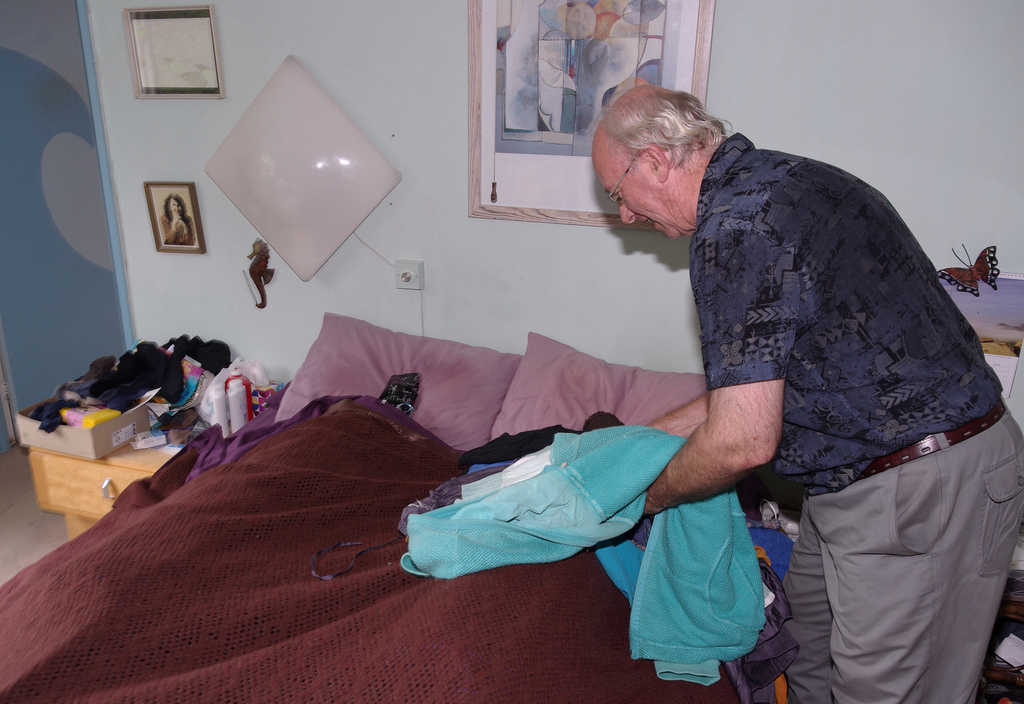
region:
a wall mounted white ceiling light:
[197, 50, 401, 285]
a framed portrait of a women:
[136, 170, 212, 265]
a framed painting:
[466, 0, 719, 229]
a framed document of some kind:
[121, 0, 224, 105]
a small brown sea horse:
[238, 228, 280, 323]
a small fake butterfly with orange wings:
[927, 237, 1007, 310]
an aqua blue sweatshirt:
[396, 421, 771, 690]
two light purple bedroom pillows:
[269, 307, 712, 454]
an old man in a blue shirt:
[583, 73, 1013, 702]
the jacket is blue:
[402, 416, 770, 682]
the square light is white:
[200, 53, 403, 281]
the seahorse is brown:
[242, 239, 278, 310]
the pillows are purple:
[276, 309, 710, 453]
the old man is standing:
[593, 83, 1021, 700]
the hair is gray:
[599, 83, 727, 166]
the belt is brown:
[860, 391, 1010, 478]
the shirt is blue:
[694, 132, 1002, 503]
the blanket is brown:
[1, 410, 739, 701]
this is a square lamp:
[162, 48, 441, 284]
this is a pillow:
[283, 291, 511, 460]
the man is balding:
[476, 47, 783, 288]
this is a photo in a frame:
[133, 133, 222, 266]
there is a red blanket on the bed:
[4, 410, 769, 702]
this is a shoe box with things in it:
[7, 372, 163, 471]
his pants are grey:
[789, 358, 1020, 692]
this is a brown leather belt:
[811, 418, 1017, 501]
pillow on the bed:
[522, 354, 602, 430]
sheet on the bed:
[525, 544, 742, 628]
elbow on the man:
[719, 435, 783, 468]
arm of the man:
[640, 451, 735, 494]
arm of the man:
[631, 411, 696, 441]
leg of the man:
[778, 531, 947, 678]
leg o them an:
[776, 549, 835, 651]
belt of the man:
[924, 436, 951, 455]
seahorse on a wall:
[241, 233, 283, 314]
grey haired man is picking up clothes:
[392, 73, 1022, 702]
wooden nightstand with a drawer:
[20, 405, 217, 555]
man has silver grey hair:
[570, 72, 1022, 702]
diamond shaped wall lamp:
[201, 50, 408, 289]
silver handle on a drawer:
[98, 474, 118, 503]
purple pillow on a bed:
[266, 301, 523, 461]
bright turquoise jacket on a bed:
[397, 416, 771, 693]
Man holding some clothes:
[582, 132, 1012, 684]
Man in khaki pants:
[575, 133, 1010, 690]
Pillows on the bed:
[293, 301, 775, 516]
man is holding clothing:
[589, 81, 1022, 702]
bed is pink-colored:
[2, 310, 783, 702]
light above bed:
[201, 53, 402, 284]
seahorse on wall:
[247, 234, 276, 310]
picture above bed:
[466, 0, 719, 233]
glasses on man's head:
[601, 151, 649, 202]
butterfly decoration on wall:
[936, 240, 1000, 295]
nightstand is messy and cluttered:
[13, 329, 271, 542]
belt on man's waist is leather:
[861, 393, 1004, 479]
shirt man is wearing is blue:
[690, 130, 1004, 497]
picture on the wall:
[133, 164, 214, 256]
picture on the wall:
[117, 2, 235, 108]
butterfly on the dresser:
[926, 234, 1000, 308]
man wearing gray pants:
[765, 414, 1015, 700]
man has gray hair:
[572, 75, 728, 234]